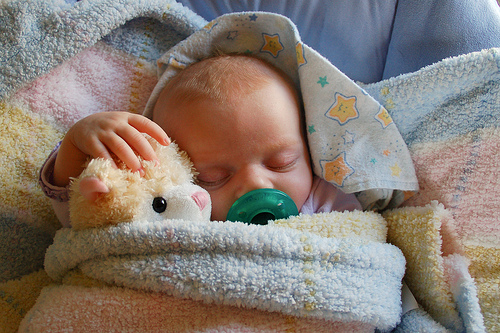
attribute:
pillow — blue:
[179, 0, 499, 87]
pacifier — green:
[218, 183, 306, 223]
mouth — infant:
[219, 185, 299, 221]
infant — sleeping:
[153, 52, 337, 222]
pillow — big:
[182, 0, 494, 55]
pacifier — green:
[216, 185, 306, 219]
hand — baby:
[33, 97, 176, 182]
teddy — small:
[62, 127, 217, 243]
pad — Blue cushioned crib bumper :
[180, 0, 499, 83]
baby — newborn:
[36, 50, 366, 266]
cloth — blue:
[136, 10, 421, 203]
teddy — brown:
[77, 144, 242, 262]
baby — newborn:
[52, 50, 313, 230]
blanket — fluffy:
[19, 197, 485, 331]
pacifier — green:
[221, 186, 303, 230]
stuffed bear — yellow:
[64, 135, 213, 229]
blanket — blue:
[79, 62, 441, 285]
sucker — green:
[221, 188, 298, 226]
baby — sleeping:
[40, 57, 394, 331]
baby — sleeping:
[37, 53, 367, 319]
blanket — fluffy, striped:
[143, 9, 426, 198]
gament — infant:
[32, 166, 373, 232]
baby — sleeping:
[32, 49, 373, 236]